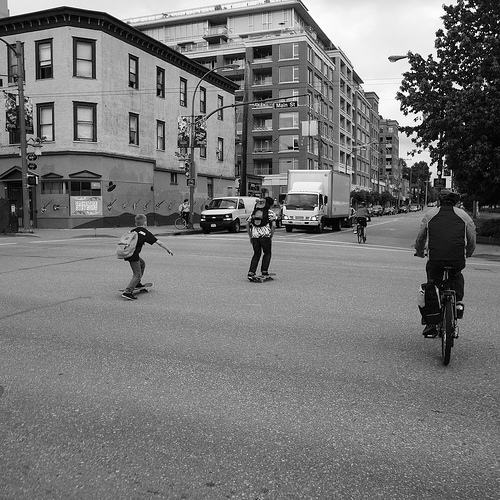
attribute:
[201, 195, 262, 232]
van — parked, white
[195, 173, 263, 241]
van — white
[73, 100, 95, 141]
window — double hung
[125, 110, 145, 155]
window — double-hung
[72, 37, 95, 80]
window — double hung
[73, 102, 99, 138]
window — double hung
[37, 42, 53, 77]
window — double hung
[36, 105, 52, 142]
window — double hung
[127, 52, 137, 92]
window — double hung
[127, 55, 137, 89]
window — double-hung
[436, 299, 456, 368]
wheel — back